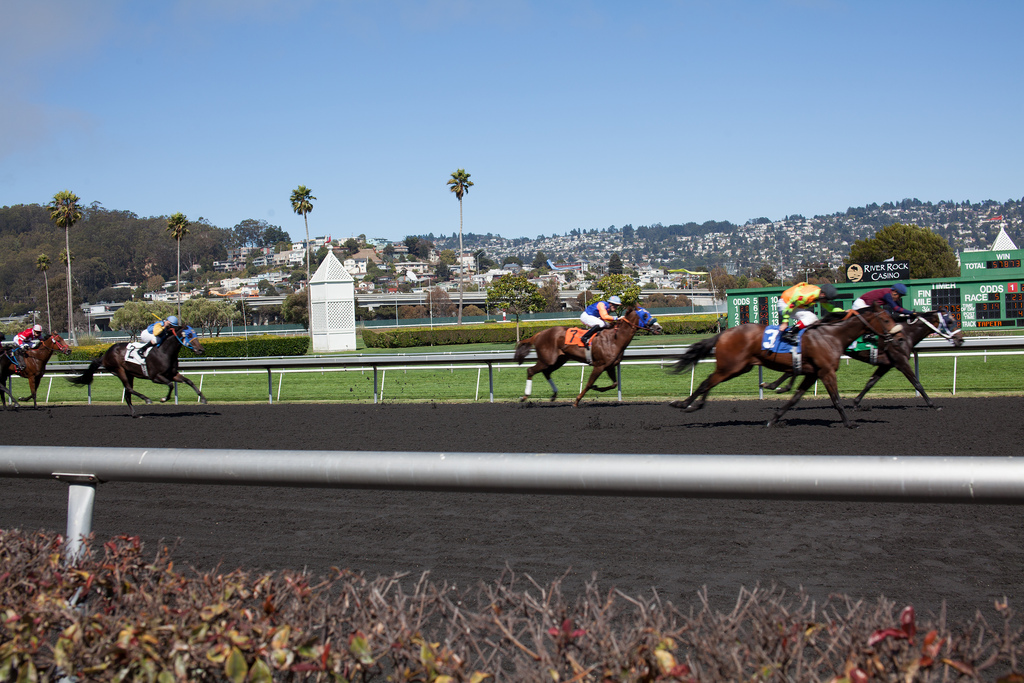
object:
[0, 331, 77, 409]
horses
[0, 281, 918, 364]
jockeys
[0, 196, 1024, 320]
hill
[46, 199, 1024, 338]
houses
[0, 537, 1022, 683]
leaves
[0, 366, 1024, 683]
grass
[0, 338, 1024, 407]
guardrail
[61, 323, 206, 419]
horses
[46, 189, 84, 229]
branch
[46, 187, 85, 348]
trees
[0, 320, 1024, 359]
hedges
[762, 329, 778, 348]
number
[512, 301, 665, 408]
horse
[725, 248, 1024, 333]
house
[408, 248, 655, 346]
building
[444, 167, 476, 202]
trees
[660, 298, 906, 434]
horse